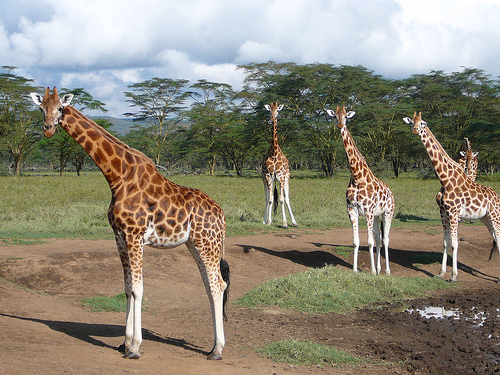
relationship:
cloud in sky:
[6, 1, 500, 103] [1, 0, 496, 57]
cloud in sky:
[6, 1, 500, 103] [72, 10, 304, 46]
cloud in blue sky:
[6, 1, 500, 103] [0, 0, 499, 119]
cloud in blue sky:
[6, 1, 500, 103] [36, 61, 184, 86]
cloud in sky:
[6, 1, 500, 103] [4, 1, 499, 113]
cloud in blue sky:
[6, 1, 500, 103] [1, 0, 499, 107]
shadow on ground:
[238, 240, 363, 272] [1, 173, 498, 373]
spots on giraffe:
[127, 181, 166, 226] [27, 84, 227, 362]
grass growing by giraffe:
[246, 263, 351, 309] [30, 86, 231, 360]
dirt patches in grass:
[0, 220, 499, 374] [4, 170, 498, 362]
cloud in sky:
[6, 1, 353, 70] [4, 1, 499, 113]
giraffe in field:
[325, 103, 396, 277] [1, 167, 496, 373]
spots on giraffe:
[146, 208, 183, 236] [27, 84, 227, 362]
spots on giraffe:
[452, 185, 479, 211] [405, 110, 497, 281]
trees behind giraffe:
[6, 64, 498, 179] [27, 84, 227, 362]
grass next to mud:
[281, 273, 342, 325] [366, 293, 474, 361]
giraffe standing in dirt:
[398, 105, 498, 282] [145, 255, 211, 372]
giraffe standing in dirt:
[325, 103, 396, 277] [145, 255, 211, 372]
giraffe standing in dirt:
[263, 95, 295, 229] [145, 255, 211, 372]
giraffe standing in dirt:
[460, 135, 479, 182] [145, 255, 211, 372]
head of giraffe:
[21, 81, 75, 143] [21, 80, 241, 365]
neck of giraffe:
[69, 110, 171, 218] [27, 68, 253, 368]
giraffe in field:
[27, 84, 227, 362] [1, 167, 496, 373]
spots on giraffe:
[267, 157, 290, 186] [261, 99, 298, 228]